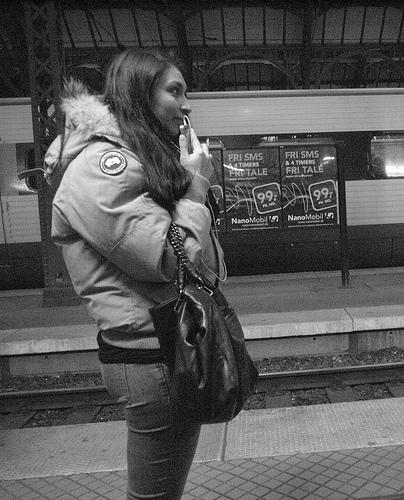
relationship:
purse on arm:
[130, 230, 260, 435] [170, 145, 227, 282]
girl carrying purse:
[40, 50, 263, 498] [130, 230, 260, 435]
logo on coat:
[97, 148, 128, 176] [63, 139, 213, 284]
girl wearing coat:
[40, 50, 263, 498] [63, 139, 213, 284]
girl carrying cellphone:
[40, 50, 263, 498] [174, 117, 200, 144]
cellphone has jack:
[174, 117, 200, 144] [204, 193, 237, 297]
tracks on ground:
[272, 360, 402, 406] [10, 315, 402, 414]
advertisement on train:
[212, 133, 346, 229] [8, 108, 403, 295]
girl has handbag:
[40, 50, 263, 498] [130, 230, 260, 435]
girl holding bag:
[40, 50, 263, 498] [148, 283, 257, 428]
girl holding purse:
[55, 50, 216, 278] [130, 230, 260, 435]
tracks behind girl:
[272, 360, 402, 406] [55, 50, 216, 278]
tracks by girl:
[272, 360, 402, 406] [55, 50, 216, 278]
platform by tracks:
[17, 273, 402, 368] [272, 360, 402, 406]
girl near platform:
[55, 50, 216, 278] [17, 273, 402, 368]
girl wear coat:
[55, 50, 216, 278] [63, 139, 213, 284]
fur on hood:
[76, 88, 106, 125] [27, 91, 126, 162]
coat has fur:
[63, 139, 213, 284] [76, 88, 106, 125]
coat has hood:
[63, 139, 213, 284] [27, 91, 126, 162]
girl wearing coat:
[55, 50, 216, 278] [63, 139, 213, 284]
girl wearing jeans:
[55, 50, 216, 278] [95, 361, 199, 493]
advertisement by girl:
[212, 133, 346, 229] [55, 50, 216, 278]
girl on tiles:
[55, 50, 216, 278] [243, 469, 361, 496]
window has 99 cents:
[211, 140, 402, 231] [289, 181, 347, 218]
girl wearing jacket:
[40, 50, 263, 498] [39, 113, 182, 354]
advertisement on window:
[212, 133, 346, 229] [211, 140, 402, 231]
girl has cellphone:
[55, 50, 216, 278] [170, 110, 200, 144]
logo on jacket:
[97, 148, 128, 176] [39, 113, 182, 354]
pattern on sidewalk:
[272, 469, 295, 485] [239, 464, 397, 497]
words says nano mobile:
[284, 211, 338, 223] [289, 214, 346, 226]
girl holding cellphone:
[55, 50, 216, 278] [170, 110, 200, 144]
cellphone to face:
[170, 110, 200, 144] [151, 60, 191, 144]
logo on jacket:
[102, 153, 135, 176] [39, 113, 182, 354]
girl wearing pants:
[40, 50, 263, 498] [95, 361, 199, 493]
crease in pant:
[144, 362, 187, 500] [95, 361, 199, 493]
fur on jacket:
[76, 88, 106, 125] [39, 113, 182, 354]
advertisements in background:
[212, 133, 346, 229] [200, 115, 402, 278]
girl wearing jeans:
[40, 50, 263, 498] [95, 361, 199, 493]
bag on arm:
[153, 283, 257, 428] [170, 145, 227, 282]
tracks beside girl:
[272, 360, 402, 406] [40, 50, 263, 498]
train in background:
[8, 108, 403, 295] [200, 115, 402, 278]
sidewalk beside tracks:
[239, 464, 397, 497] [272, 360, 402, 406]